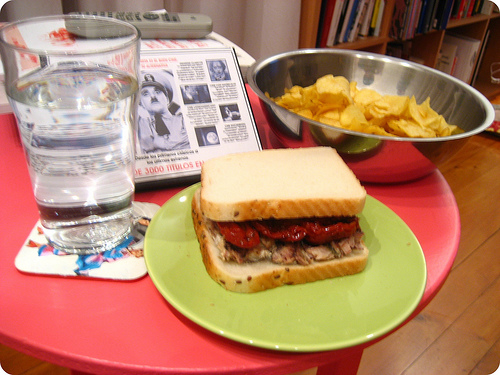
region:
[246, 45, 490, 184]
a stainless steel bowl containing chips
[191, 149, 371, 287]
a chicken sandwich with red peppers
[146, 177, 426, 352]
a green plate with a chicken sandwich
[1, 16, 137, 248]
a glass of water on a red table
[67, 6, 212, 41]
a gray remote on a DVD case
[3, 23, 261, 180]
a DVD case with a picture of Charlie Chaplin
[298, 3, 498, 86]
a wooden bookcase with rows of books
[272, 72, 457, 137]
plain chips in a stainless steel bowl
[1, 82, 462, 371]
a red table on hardwood floor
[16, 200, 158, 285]
a white coaster on a red table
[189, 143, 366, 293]
Sandwich with white bread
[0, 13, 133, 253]
Tall glass of water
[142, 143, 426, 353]
Sandwich on a green plate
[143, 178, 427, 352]
Green plate on a red table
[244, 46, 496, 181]
Metal bowl of plain potato chips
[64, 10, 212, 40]
Gray remote control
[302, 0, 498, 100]
Books on book shelves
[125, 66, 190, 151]
printed picture of Hitler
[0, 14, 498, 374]
Food sitting on a red table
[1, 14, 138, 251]
Water in a glass cup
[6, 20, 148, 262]
Glass of water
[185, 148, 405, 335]
A sandwich with meat and vegetables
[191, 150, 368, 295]
A sandwich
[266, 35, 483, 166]
A bowl of chips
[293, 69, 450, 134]
Potato chips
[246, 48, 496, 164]
Bowl of potato chips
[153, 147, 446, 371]
A sandwich on a green plate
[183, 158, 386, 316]
A sandwich made with white bread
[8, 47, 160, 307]
A glass on a coaster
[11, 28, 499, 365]
Lunch on a red table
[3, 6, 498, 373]
Dinner and movie sitting on the table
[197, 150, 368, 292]
A sandwich is on the plate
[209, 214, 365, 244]
There are red peppers on the sandwich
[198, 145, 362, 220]
The sandwich bread is white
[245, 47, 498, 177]
The chips are in a silver bowl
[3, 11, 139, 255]
A tall glass of water on the table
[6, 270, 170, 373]
The table is a wooden table painted pink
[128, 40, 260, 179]
The movie is set out and ready to be watched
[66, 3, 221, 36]
A remote to the DVD on the table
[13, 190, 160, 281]
The coaster under the glass of water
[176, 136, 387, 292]
a delicious sandwich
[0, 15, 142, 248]
a cold glass of water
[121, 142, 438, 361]
a sandwich on a green plate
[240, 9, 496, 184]
a bowl of potato chips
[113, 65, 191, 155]
a picture of Charlie Chaplin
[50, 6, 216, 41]
a gray colored remote control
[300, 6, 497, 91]
a wooden bookcase filled with books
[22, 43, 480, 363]
a red table holding lunch and some other things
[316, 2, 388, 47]
several books on a shelf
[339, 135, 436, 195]
the reflection of a red table on the side of a silver bowl